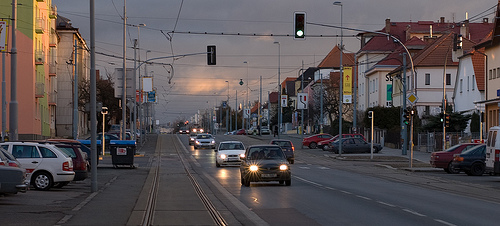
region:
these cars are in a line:
[80, 30, 431, 221]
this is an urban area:
[57, 46, 450, 186]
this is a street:
[111, 28, 397, 201]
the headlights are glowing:
[160, 107, 315, 208]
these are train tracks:
[153, 171, 237, 209]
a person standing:
[269, 121, 280, 138]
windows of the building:
[456, 74, 476, 94]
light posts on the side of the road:
[218, 2, 423, 173]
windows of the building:
[487, 64, 499, 84]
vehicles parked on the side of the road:
[425, 122, 499, 179]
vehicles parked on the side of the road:
[299, 128, 384, 156]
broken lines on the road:
[320, 178, 457, 224]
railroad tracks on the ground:
[132, 133, 232, 224]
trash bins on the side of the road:
[76, 134, 139, 173]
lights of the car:
[247, 161, 288, 173]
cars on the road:
[175, 123, 308, 190]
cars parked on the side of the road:
[0, 134, 90, 197]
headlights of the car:
[248, 161, 288, 173]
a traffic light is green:
[292, 9, 307, 39]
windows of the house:
[420, 69, 454, 88]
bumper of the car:
[55, 169, 77, 182]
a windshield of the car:
[244, 143, 286, 161]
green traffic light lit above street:
[294, 12, 307, 39]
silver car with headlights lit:
[235, 140, 302, 188]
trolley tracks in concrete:
[140, 120, 211, 221]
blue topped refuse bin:
[108, 135, 142, 171]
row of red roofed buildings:
[237, 10, 499, 178]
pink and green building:
[6, 0, 72, 130]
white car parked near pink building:
[1, 135, 73, 189]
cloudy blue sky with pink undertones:
[82, 0, 489, 126]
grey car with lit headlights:
[239, 141, 294, 190]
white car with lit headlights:
[211, 138, 245, 168]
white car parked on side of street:
[3, 131, 75, 190]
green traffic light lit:
[291, 8, 314, 40]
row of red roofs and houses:
[243, 9, 488, 176]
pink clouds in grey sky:
[173, 24, 285, 116]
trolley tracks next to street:
[126, 117, 231, 224]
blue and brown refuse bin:
[105, 134, 141, 173]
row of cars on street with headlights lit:
[175, 123, 308, 211]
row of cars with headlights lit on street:
[176, 116, 295, 214]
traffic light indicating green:
[288, 7, 313, 43]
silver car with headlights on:
[238, 140, 295, 189]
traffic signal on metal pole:
[292, 11, 414, 168]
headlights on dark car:
[239, 144, 293, 186]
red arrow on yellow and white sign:
[341, 64, 353, 104]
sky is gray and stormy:
[52, 1, 499, 131]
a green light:
[291, 31, 307, 38]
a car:
[240, 146, 290, 186]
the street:
[291, 186, 321, 220]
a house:
[365, 70, 382, 108]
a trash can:
[108, 140, 134, 165]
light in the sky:
[180, 72, 221, 92]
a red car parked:
[430, 145, 450, 165]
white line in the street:
[353, 195, 388, 206]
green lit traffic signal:
[289, 8, 309, 42]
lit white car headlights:
[243, 163, 288, 176]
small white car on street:
[210, 137, 248, 172]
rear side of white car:
[0, 136, 76, 194]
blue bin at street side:
[103, 135, 138, 170]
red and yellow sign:
[335, 63, 357, 97]